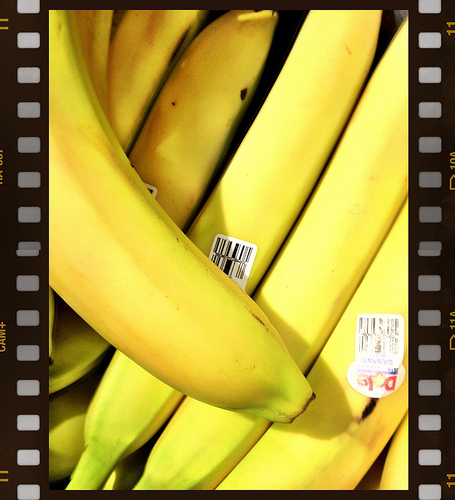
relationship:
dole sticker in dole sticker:
[344, 353, 407, 399] [344, 353, 407, 399]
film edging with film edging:
[0, 0, 50, 497] [403, 4, 451, 498]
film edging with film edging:
[0, 0, 50, 497] [0, 0, 50, 497]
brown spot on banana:
[235, 85, 250, 103] [31, 1, 324, 422]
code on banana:
[354, 317, 403, 373] [194, 201, 415, 498]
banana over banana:
[31, 1, 324, 422] [131, 19, 407, 488]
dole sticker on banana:
[344, 353, 411, 399] [31, 1, 324, 422]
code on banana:
[354, 317, 403, 373] [131, 19, 407, 488]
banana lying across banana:
[54, 15, 323, 429] [109, 23, 383, 496]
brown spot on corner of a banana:
[235, 85, 250, 103] [41, 5, 275, 400]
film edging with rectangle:
[0, 0, 50, 497] [16, 31, 40, 47]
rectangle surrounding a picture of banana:
[16, 31, 40, 47] [54, 15, 323, 429]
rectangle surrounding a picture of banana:
[16, 100, 41, 118] [75, 7, 115, 155]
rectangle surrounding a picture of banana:
[16, 169, 41, 187] [110, 9, 206, 152]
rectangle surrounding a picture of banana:
[417, 66, 443, 84] [41, 5, 275, 400]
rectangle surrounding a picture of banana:
[418, 134, 442, 152] [58, 11, 383, 491]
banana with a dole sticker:
[48, 20, 343, 439] [339, 302, 411, 398]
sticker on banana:
[206, 233, 258, 289] [58, 11, 383, 491]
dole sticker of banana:
[344, 353, 407, 399] [214, 192, 409, 489]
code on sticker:
[354, 317, 403, 373] [347, 358, 404, 395]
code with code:
[354, 317, 403, 373] [354, 317, 397, 372]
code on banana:
[208, 235, 236, 278] [54, 15, 323, 429]